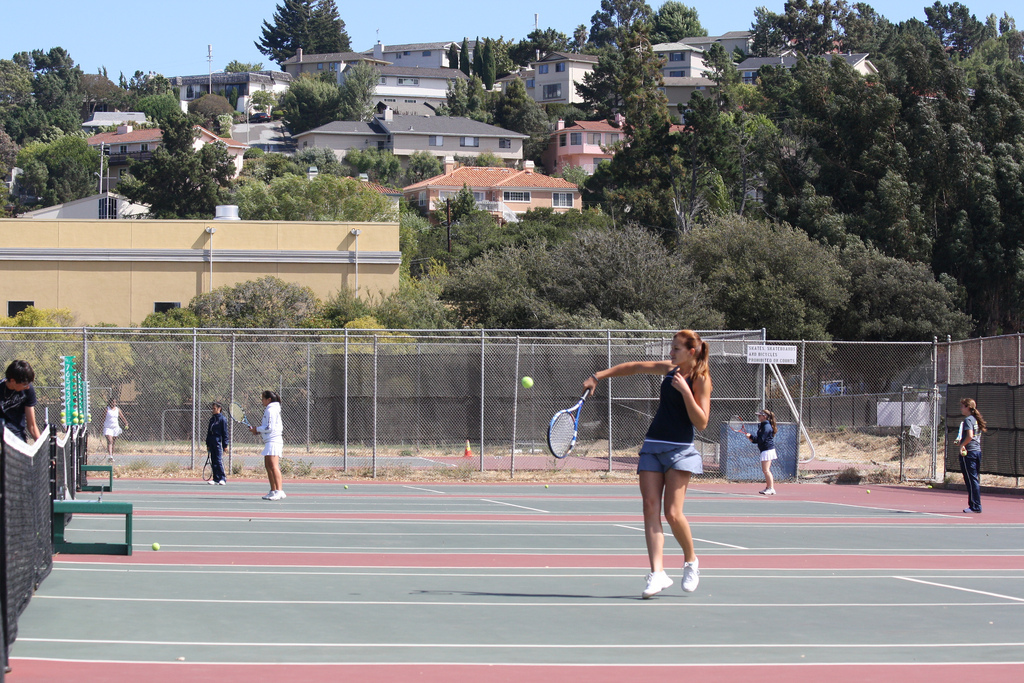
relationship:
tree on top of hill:
[666, 202, 862, 370] [2, 34, 1018, 339]